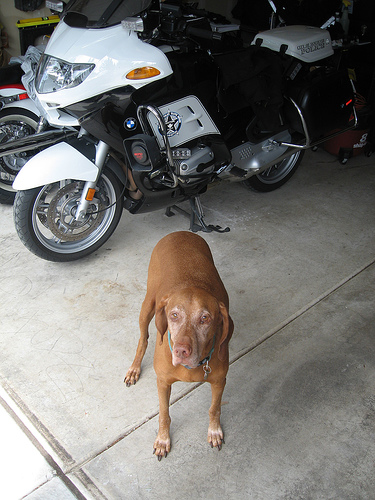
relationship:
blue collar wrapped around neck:
[161, 325, 227, 380] [157, 317, 230, 372]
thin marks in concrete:
[29, 329, 110, 408] [0, 146, 375, 496]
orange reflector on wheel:
[84, 184, 97, 205] [12, 168, 126, 262]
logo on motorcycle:
[121, 115, 138, 132] [10, 0, 336, 266]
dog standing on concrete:
[123, 230, 236, 461] [8, 279, 155, 491]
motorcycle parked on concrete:
[15, 8, 349, 265] [2, 224, 163, 496]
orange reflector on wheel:
[85, 188, 96, 201] [12, 168, 126, 262]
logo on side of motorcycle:
[121, 115, 138, 132] [10, 0, 336, 266]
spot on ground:
[65, 264, 140, 329] [3, 107, 364, 497]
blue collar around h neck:
[167, 327, 216, 371] [150, 303, 225, 383]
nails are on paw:
[149, 441, 171, 460] [152, 443, 173, 458]